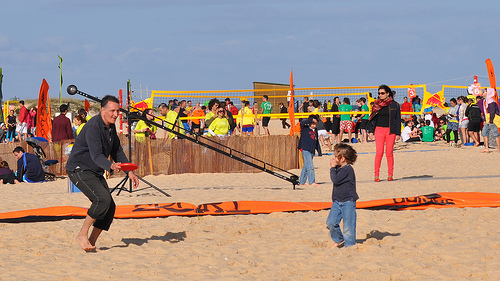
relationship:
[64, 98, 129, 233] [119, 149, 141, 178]
man with frisbee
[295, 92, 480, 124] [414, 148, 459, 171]
people on beach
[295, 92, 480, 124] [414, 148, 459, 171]
people staanding on beach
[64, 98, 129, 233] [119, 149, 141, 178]
man throwing frisbee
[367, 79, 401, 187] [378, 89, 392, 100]
woman wearing sunglasses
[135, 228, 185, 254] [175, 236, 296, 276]
shadow on sand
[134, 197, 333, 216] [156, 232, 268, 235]
banner on ground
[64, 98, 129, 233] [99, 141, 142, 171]
man throwing disc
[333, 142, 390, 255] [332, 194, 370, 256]
kid wearing jeans